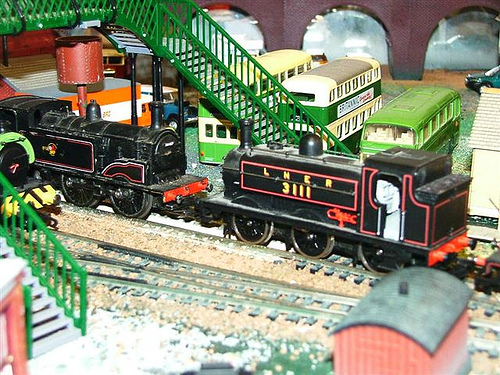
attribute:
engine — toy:
[210, 126, 481, 283]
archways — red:
[192, 13, 497, 78]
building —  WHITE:
[466, 97, 498, 247]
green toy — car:
[355, 87, 446, 136]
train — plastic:
[0, 95, 472, 272]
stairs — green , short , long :
[120, 1, 354, 159]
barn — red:
[323, 260, 483, 373]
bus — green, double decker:
[197, 22, 312, 167]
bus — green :
[375, 67, 471, 165]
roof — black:
[326, 265, 474, 357]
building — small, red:
[311, 245, 468, 373]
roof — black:
[330, 248, 471, 348]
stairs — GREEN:
[117, 0, 357, 178]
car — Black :
[231, 131, 484, 266]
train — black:
[0, 84, 495, 257]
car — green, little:
[464, 62, 484, 86]